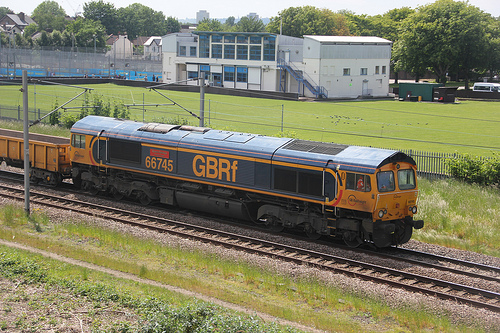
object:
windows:
[393, 167, 422, 190]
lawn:
[351, 102, 488, 138]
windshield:
[373, 163, 418, 196]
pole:
[16, 73, 36, 212]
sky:
[2, 0, 498, 27]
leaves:
[392, 0, 500, 77]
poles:
[197, 75, 209, 129]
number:
[137, 149, 179, 174]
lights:
[378, 206, 392, 217]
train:
[0, 115, 426, 252]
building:
[158, 23, 403, 105]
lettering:
[186, 148, 243, 184]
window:
[381, 167, 399, 193]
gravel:
[0, 153, 492, 328]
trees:
[0, 0, 181, 69]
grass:
[2, 73, 497, 326]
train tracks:
[3, 150, 499, 312]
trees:
[390, 0, 500, 93]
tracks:
[0, 170, 500, 314]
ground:
[0, 249, 500, 333]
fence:
[330, 145, 500, 187]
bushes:
[446, 120, 484, 189]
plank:
[133, 214, 177, 227]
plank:
[188, 223, 224, 239]